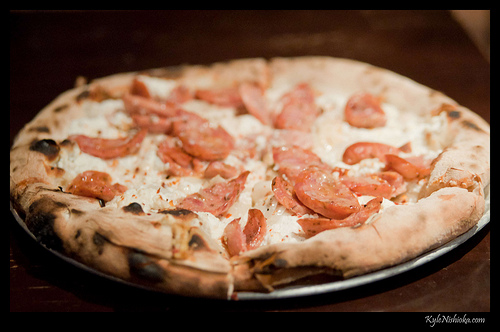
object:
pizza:
[14, 54, 497, 301]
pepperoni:
[178, 118, 234, 159]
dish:
[8, 55, 490, 300]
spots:
[123, 201, 146, 215]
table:
[0, 12, 495, 316]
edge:
[7, 200, 232, 303]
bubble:
[267, 196, 280, 211]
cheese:
[252, 188, 273, 207]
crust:
[8, 63, 236, 302]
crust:
[6, 54, 495, 301]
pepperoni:
[174, 170, 250, 215]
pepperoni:
[295, 168, 359, 219]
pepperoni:
[271, 175, 312, 215]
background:
[0, 0, 500, 332]